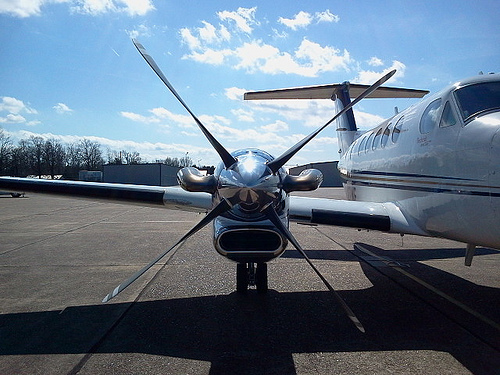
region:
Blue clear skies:
[58, 40, 104, 83]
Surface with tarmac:
[62, 220, 118, 274]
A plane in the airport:
[159, 75, 339, 263]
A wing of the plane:
[302, 193, 389, 232]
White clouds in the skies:
[205, 19, 280, 72]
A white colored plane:
[389, 131, 463, 217]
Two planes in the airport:
[200, 111, 497, 280]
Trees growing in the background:
[25, 139, 89, 168]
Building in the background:
[108, 150, 174, 187]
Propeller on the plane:
[209, 159, 290, 226]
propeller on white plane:
[81, 46, 368, 296]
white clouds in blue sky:
[12, 1, 49, 45]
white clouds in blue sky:
[38, 82, 70, 100]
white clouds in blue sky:
[197, 29, 244, 66]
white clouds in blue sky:
[74, 53, 121, 93]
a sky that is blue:
[201, 18, 408, 115]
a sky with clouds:
[184, 15, 334, 112]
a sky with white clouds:
[179, 23, 429, 148]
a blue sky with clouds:
[149, 12, 422, 155]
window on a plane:
[458, 81, 496, 118]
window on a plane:
[441, 108, 460, 128]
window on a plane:
[419, 90, 444, 135]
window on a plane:
[362, 125, 375, 161]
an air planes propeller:
[98, 39, 400, 334]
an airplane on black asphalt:
[1, 36, 499, 336]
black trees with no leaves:
[0, 126, 206, 182]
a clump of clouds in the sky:
[168, 2, 407, 96]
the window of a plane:
[453, 78, 499, 128]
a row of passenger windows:
[342, 111, 407, 161]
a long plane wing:
[1, 171, 422, 238]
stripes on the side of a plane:
[338, 163, 498, 202]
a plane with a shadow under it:
[1, 36, 499, 373]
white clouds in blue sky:
[85, 99, 152, 136]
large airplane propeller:
[88, 35, 384, 333]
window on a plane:
[387, 117, 403, 147]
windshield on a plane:
[449, 85, 499, 126]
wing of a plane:
[0, 170, 407, 239]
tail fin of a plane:
[243, 82, 428, 137]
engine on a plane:
[191, 163, 313, 278]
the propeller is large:
[96, 36, 396, 336]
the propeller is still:
[100, 37, 396, 334]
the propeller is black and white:
[101, 35, 396, 333]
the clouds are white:
[0, 0, 499, 168]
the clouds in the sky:
[0, 0, 498, 169]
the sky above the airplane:
[0, 0, 497, 333]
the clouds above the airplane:
[1, 0, 497, 332]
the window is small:
[391, 115, 402, 143]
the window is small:
[381, 122, 391, 149]